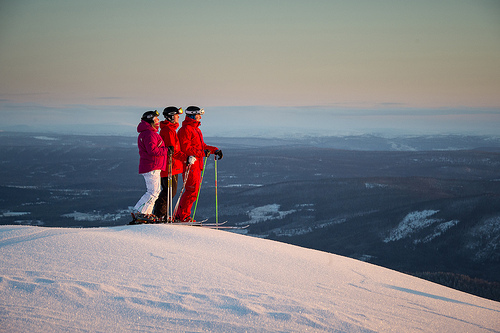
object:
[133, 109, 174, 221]
skier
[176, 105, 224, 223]
skier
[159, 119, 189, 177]
red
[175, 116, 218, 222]
red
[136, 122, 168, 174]
coat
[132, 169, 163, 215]
pants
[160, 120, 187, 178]
coat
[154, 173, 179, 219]
pants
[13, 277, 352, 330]
tracks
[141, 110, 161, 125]
helmet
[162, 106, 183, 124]
helmet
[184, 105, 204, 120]
helmet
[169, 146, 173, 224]
ski poles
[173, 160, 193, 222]
ski poles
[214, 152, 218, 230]
ski poles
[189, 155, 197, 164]
glove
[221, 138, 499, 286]
distance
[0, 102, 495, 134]
clouds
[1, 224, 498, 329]
mountain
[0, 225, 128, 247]
shadow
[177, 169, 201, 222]
pants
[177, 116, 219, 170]
coat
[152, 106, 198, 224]
middle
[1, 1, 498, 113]
sky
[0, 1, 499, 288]
background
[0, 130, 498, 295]
land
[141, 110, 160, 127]
head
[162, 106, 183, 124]
head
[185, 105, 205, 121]
head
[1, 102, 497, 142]
mountain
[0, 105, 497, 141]
horizon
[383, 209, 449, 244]
snow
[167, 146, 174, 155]
hand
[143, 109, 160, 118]
snow goggles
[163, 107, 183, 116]
snow goggles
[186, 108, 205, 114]
snow goggles